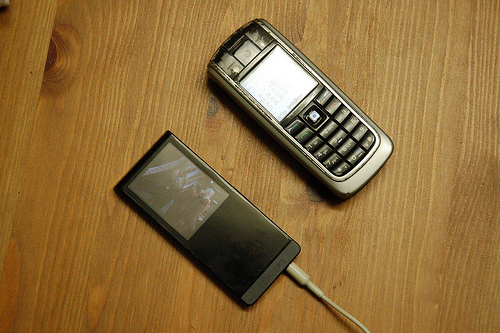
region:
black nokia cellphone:
[207, 19, 391, 196]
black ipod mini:
[109, 128, 307, 316]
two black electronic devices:
[101, 11, 396, 301]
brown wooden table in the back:
[1, 1, 493, 328]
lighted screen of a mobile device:
[240, 48, 312, 123]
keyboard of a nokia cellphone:
[287, 80, 374, 185]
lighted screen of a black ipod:
[122, 143, 228, 241]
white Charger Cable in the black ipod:
[282, 259, 377, 330]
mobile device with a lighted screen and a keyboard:
[217, 19, 394, 208]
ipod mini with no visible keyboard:
[111, 136, 307, 311]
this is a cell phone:
[206, 10, 371, 168]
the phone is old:
[216, 11, 361, 176]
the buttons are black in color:
[316, 118, 354, 148]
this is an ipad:
[156, 178, 301, 288]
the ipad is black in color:
[204, 223, 277, 270]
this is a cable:
[281, 253, 342, 303]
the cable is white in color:
[283, 267, 333, 307]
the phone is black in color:
[230, 30, 258, 65]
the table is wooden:
[376, 182, 474, 320]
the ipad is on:
[162, 174, 210, 214]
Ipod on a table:
[108, 119, 326, 312]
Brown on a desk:
[13, 52, 174, 248]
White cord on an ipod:
[281, 248, 383, 331]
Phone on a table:
[206, 14, 421, 223]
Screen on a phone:
[243, 46, 321, 128]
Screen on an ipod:
[126, 145, 228, 244]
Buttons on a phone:
[281, 81, 375, 171]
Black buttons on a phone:
[306, 100, 378, 175]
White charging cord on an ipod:
[266, 247, 389, 332]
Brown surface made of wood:
[88, 91, 453, 299]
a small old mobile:
[207, 27, 419, 197]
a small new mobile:
[102, 144, 306, 301]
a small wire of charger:
[291, 257, 393, 331]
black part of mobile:
[198, 218, 313, 286]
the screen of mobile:
[136, 156, 241, 232]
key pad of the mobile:
[289, 100, 374, 173]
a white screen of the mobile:
[234, 57, 323, 116]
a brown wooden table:
[29, 11, 496, 322]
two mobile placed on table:
[0, 23, 425, 315]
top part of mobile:
[228, 42, 270, 64]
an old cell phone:
[192, 14, 409, 212]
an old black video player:
[93, 130, 304, 310]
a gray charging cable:
[289, 262, 366, 331]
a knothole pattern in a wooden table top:
[40, 34, 64, 82]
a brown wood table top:
[385, 18, 478, 137]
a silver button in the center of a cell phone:
[303, 103, 323, 123]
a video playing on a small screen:
[157, 164, 213, 226]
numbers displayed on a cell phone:
[248, 65, 303, 109]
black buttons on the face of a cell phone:
[302, 111, 371, 168]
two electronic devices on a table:
[58, 0, 444, 324]